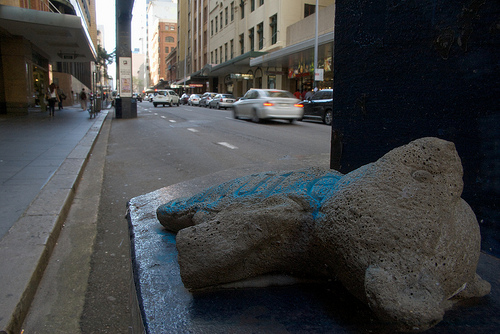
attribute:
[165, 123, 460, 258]
bear — teddy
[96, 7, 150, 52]
sky — clear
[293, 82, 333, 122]
car — parked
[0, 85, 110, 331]
sidewalk — next to, curb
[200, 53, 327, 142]
car — white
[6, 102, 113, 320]
curb — street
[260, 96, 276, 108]
light — red, tail, car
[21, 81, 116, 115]
people — background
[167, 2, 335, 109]
building — brown, background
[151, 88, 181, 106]
vehicle — white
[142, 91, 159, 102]
vehicle — white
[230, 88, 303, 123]
vehicle — white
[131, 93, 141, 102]
vehicle — white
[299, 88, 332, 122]
vehicle — white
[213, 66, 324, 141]
car — car's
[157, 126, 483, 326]
bear — dirty, teddy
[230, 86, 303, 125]
car — white, background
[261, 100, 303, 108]
taillights — car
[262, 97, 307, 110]
taillights — red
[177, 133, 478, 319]
object — stone, foreground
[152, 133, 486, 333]
object — stone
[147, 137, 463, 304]
bear — teddy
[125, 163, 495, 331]
platform — blue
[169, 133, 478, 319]
bear — teddy, dirty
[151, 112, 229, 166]
street — city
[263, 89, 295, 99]
window — back, car